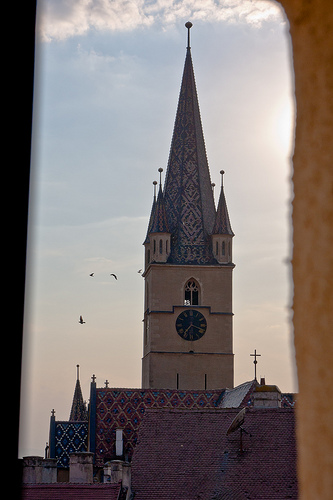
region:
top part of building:
[167, 10, 215, 57]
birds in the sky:
[78, 246, 134, 325]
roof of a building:
[169, 426, 227, 475]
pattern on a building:
[54, 413, 90, 449]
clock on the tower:
[167, 308, 215, 348]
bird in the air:
[53, 303, 89, 345]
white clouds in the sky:
[100, 4, 146, 44]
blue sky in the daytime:
[54, 59, 129, 129]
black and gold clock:
[173, 309, 207, 341]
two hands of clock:
[181, 321, 201, 336]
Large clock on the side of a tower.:
[175, 308, 208, 341]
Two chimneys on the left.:
[21, 453, 57, 487]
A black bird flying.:
[76, 312, 85, 324]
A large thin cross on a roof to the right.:
[248, 348, 260, 382]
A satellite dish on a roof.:
[221, 405, 252, 456]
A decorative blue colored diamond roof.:
[54, 418, 88, 467]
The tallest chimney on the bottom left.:
[67, 451, 94, 484]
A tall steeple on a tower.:
[142, 20, 234, 266]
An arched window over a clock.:
[181, 275, 202, 306]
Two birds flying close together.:
[88, 271, 117, 280]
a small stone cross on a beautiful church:
[49, 407, 56, 416]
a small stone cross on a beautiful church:
[89, 373, 98, 380]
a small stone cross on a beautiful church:
[105, 378, 109, 386]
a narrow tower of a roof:
[68, 360, 86, 418]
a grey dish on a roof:
[226, 407, 250, 448]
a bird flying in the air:
[77, 314, 85, 323]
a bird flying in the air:
[88, 271, 96, 277]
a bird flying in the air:
[108, 271, 117, 280]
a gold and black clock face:
[176, 309, 208, 337]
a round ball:
[184, 21, 193, 29]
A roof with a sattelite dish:
[135, 407, 287, 498]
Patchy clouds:
[34, 1, 286, 50]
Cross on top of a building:
[237, 345, 268, 385]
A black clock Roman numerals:
[164, 303, 217, 343]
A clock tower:
[138, 17, 238, 385]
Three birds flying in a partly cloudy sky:
[35, 248, 126, 330]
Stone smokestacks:
[19, 449, 100, 478]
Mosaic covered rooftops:
[42, 378, 293, 464]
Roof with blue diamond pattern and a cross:
[43, 404, 87, 462]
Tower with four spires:
[137, 1, 233, 388]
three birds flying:
[68, 256, 128, 337]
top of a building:
[67, 358, 90, 418]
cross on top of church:
[248, 342, 262, 364]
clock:
[171, 305, 219, 343]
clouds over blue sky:
[44, 5, 157, 37]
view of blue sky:
[43, 65, 147, 165]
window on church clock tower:
[175, 271, 209, 307]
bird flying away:
[78, 311, 95, 330]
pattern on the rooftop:
[106, 395, 135, 417]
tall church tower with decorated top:
[131, 57, 247, 381]